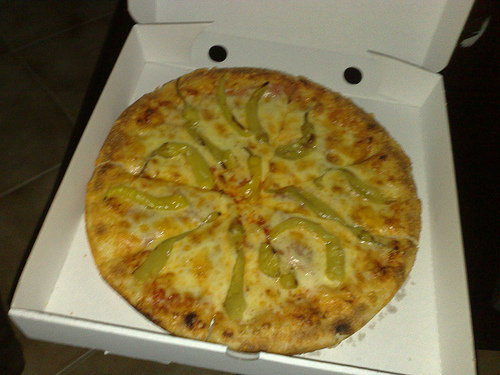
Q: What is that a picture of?
A: A pizza pie.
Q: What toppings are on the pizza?
A: Cheese and peppers.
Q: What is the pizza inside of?
A: A box.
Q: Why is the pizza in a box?
A: It is a to-go order.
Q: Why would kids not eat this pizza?
A: The peppers may be spicy.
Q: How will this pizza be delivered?
A: By a delivery person.